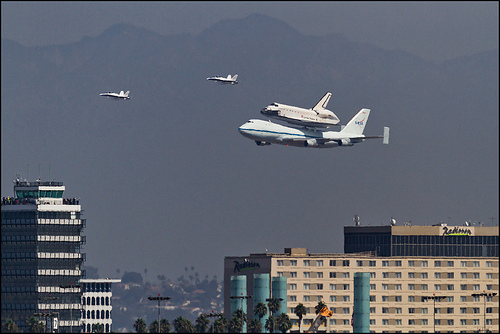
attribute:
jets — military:
[98, 62, 415, 181]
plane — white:
[237, 107, 379, 146]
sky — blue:
[5, 2, 497, 331]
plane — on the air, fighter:
[103, 87, 129, 102]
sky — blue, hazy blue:
[3, 5, 499, 292]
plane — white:
[233, 82, 393, 154]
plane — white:
[56, 82, 179, 151]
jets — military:
[266, 95, 338, 132]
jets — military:
[238, 110, 370, 147]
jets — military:
[199, 70, 247, 88]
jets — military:
[101, 87, 132, 103]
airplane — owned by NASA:
[232, 93, 408, 160]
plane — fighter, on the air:
[201, 65, 246, 92]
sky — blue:
[43, 23, 413, 68]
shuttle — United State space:
[228, 92, 380, 155]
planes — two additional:
[103, 68, 244, 103]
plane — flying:
[239, 109, 391, 149]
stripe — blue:
[236, 126, 326, 138]